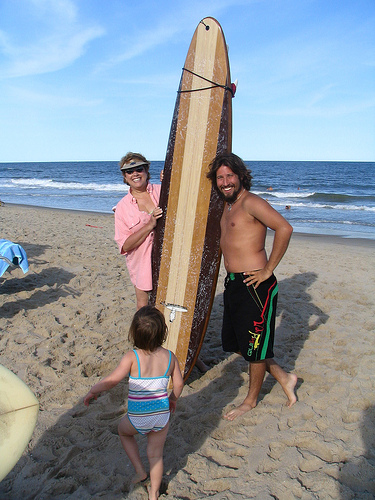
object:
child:
[82, 305, 185, 500]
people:
[253, 167, 347, 221]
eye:
[217, 173, 224, 180]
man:
[205, 152, 297, 421]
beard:
[219, 182, 242, 201]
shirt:
[113, 182, 161, 293]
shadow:
[280, 290, 332, 356]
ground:
[280, 258, 375, 364]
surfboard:
[146, 16, 235, 388]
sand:
[30, 264, 107, 350]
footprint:
[66, 290, 103, 343]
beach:
[5, 268, 127, 363]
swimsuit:
[221, 270, 279, 361]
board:
[146, 16, 236, 388]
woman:
[111, 151, 170, 292]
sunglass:
[125, 165, 144, 175]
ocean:
[0, 159, 375, 238]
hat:
[120, 153, 149, 172]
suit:
[125, 348, 171, 436]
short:
[220, 268, 280, 362]